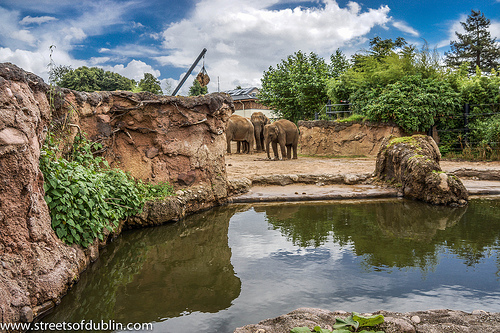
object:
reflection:
[66, 202, 244, 331]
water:
[482, 198, 497, 220]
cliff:
[4, 81, 227, 314]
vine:
[68, 124, 83, 135]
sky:
[3, 2, 497, 94]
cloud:
[348, 5, 398, 37]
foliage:
[257, 56, 494, 124]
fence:
[291, 101, 351, 119]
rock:
[377, 131, 471, 207]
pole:
[170, 48, 208, 97]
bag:
[194, 70, 211, 88]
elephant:
[265, 120, 304, 158]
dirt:
[287, 155, 338, 175]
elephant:
[223, 113, 256, 150]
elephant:
[250, 111, 266, 148]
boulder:
[290, 174, 299, 182]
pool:
[35, 204, 490, 331]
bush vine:
[94, 147, 105, 154]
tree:
[260, 51, 331, 119]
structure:
[218, 87, 298, 120]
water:
[279, 229, 302, 241]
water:
[482, 200, 499, 216]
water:
[390, 200, 409, 217]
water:
[249, 208, 275, 219]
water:
[120, 223, 145, 240]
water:
[456, 286, 494, 305]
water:
[210, 309, 228, 330]